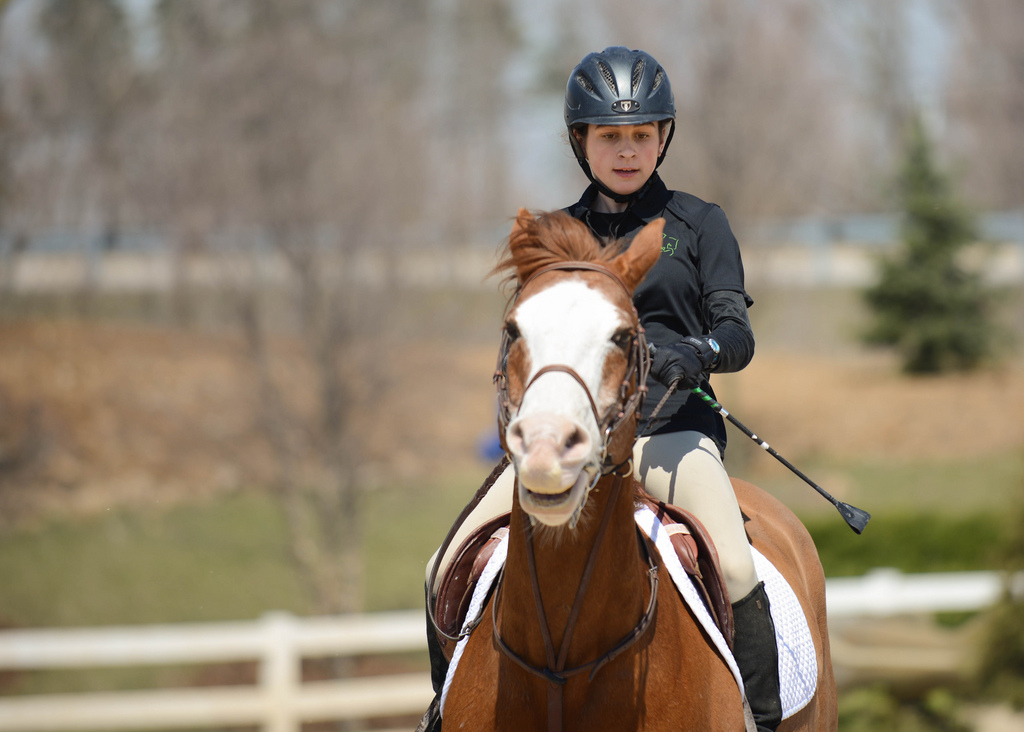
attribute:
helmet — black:
[561, 46, 678, 194]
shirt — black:
[477, 126, 758, 515]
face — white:
[490, 292, 674, 565]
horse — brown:
[362, 168, 838, 728]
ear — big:
[602, 163, 691, 302]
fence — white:
[41, 555, 389, 713]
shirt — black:
[545, 182, 723, 433]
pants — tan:
[417, 420, 778, 637]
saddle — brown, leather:
[365, 489, 739, 677]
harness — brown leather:
[454, 238, 655, 712]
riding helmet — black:
[554, 57, 688, 140]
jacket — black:
[484, 175, 757, 472]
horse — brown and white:
[376, 219, 824, 729]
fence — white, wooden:
[18, 605, 995, 707]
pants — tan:
[476, 404, 768, 729]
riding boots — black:
[398, 571, 785, 718]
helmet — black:
[504, 54, 706, 158]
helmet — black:
[549, 42, 710, 151]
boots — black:
[378, 571, 811, 727]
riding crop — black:
[601, 327, 878, 544]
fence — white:
[2, 571, 1022, 729]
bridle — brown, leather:
[488, 264, 659, 686]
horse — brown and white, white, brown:
[427, 206, 842, 727]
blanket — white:
[436, 498, 819, 725]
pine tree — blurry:
[849, 107, 1020, 376]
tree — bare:
[138, 3, 443, 729]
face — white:
[494, 275, 631, 528]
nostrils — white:
[509, 413, 589, 452]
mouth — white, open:
[514, 463, 594, 516]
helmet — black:
[566, 44, 675, 200]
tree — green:
[859, 104, 1009, 377]